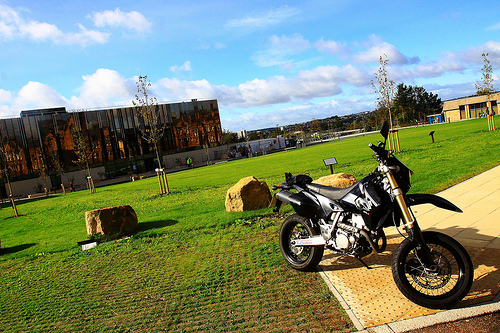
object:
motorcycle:
[267, 118, 475, 311]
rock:
[84, 204, 140, 237]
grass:
[0, 116, 500, 332]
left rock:
[224, 175, 273, 212]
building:
[0, 99, 227, 199]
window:
[102, 112, 142, 156]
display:
[322, 157, 339, 175]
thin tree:
[132, 75, 171, 195]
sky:
[0, 0, 495, 90]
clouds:
[1, 0, 155, 51]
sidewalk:
[335, 207, 499, 297]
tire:
[389, 230, 474, 306]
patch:
[31, 209, 76, 244]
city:
[0, 90, 500, 332]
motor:
[319, 212, 381, 258]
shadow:
[317, 225, 499, 308]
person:
[186, 158, 193, 169]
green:
[231, 162, 251, 173]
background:
[0, 0, 500, 136]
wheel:
[277, 213, 325, 271]